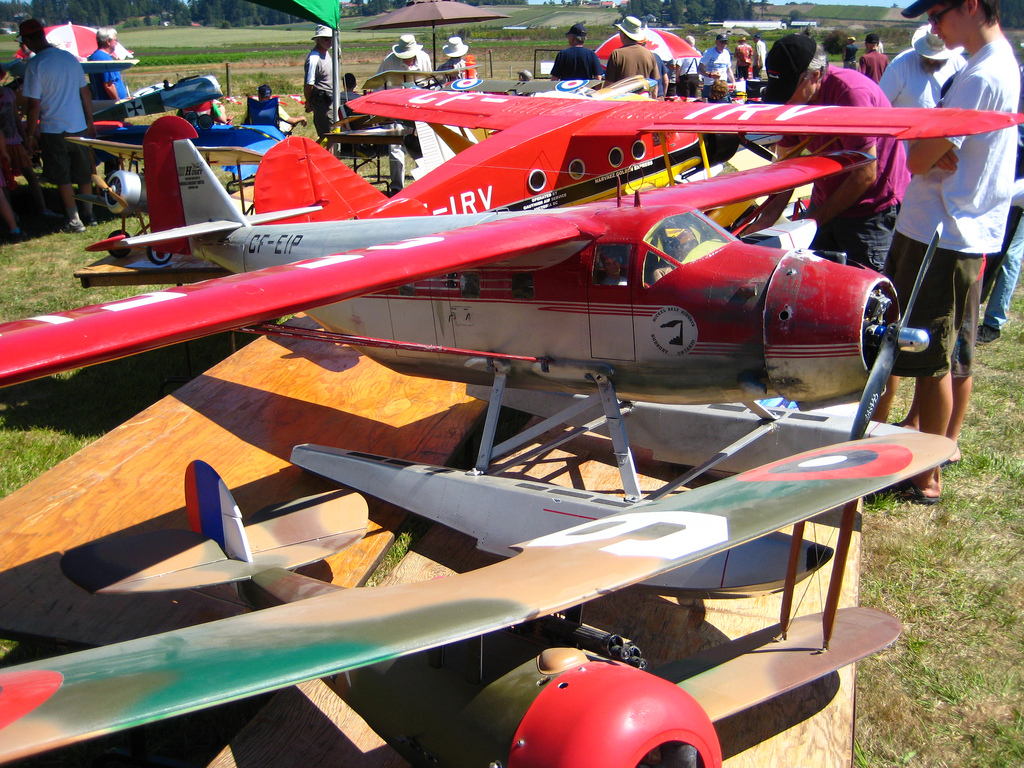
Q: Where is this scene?
A: It is outdoors.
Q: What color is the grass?
A: It is brown and green.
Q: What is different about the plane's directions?
A: They are not all facing in the same direction.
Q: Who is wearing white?
A: A guy in bermuda shorts, standing by the planes.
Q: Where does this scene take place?
A: It is an outdoor scene.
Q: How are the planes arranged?
A: They are grouped together.